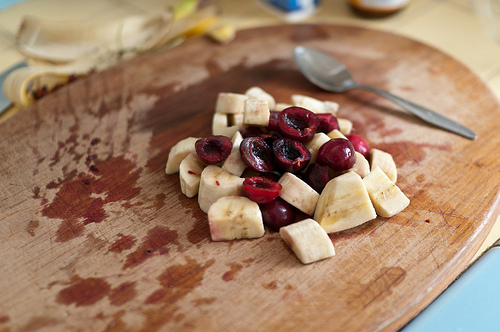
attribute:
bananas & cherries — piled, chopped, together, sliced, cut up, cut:
[177, 92, 355, 257]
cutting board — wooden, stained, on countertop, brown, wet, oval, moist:
[50, 249, 248, 306]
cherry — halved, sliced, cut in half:
[276, 102, 316, 140]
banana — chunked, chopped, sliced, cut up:
[320, 176, 364, 232]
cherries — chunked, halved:
[232, 101, 344, 175]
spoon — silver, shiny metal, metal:
[274, 47, 479, 137]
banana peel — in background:
[6, 25, 275, 56]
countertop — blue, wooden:
[455, 299, 486, 327]